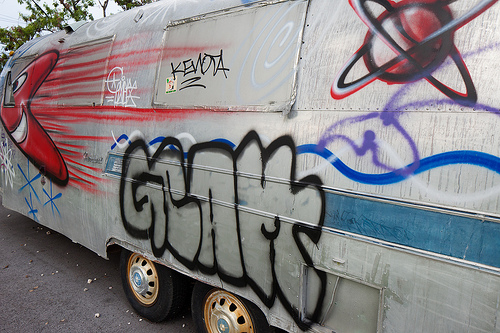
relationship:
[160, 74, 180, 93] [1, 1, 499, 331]
sticker on van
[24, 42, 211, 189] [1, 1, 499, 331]
red paint sprayed on van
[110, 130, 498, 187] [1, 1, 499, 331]
blue paint sprayed on van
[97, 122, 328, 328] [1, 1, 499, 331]
graffiti painted on van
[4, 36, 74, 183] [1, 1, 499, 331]
design painted on van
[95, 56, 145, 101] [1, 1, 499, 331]
letters are painted on van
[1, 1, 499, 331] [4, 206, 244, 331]
van parked in parking lot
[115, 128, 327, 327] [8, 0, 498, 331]
graffiti on bus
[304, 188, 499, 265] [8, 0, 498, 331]
stripe on bus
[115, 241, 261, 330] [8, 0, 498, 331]
tires on bus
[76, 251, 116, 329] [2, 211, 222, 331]
rocks are on road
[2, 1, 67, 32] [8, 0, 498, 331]
green tree are on bus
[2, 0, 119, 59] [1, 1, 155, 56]
sky behind trees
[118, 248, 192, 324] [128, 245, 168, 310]
tires on tire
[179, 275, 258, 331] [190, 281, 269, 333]
tire on tire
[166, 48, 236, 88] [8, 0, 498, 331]
graffiti on bus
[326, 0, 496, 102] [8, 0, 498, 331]
graffiti on bus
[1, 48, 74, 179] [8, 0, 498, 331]
graffiti on bus